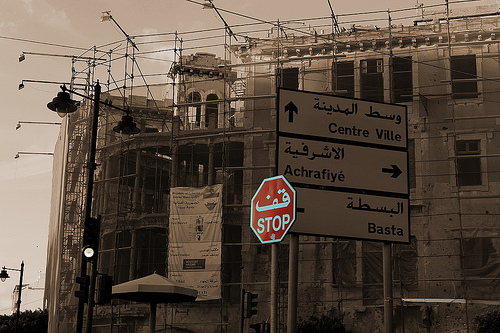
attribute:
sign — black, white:
[275, 86, 409, 248]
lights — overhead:
[14, 47, 81, 163]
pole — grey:
[268, 246, 276, 331]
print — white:
[255, 190, 289, 234]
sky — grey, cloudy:
[1, 0, 171, 268]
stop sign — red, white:
[249, 173, 296, 243]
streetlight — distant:
[1, 263, 28, 330]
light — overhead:
[17, 79, 94, 92]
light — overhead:
[14, 116, 63, 131]